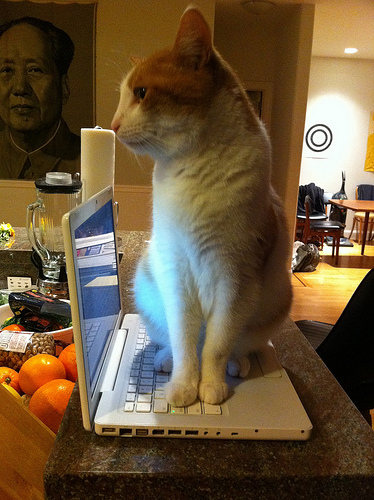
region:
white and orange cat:
[106, 19, 305, 407]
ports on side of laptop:
[94, 415, 317, 441]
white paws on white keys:
[155, 368, 239, 415]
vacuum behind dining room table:
[325, 167, 353, 250]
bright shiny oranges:
[0, 357, 73, 427]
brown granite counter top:
[220, 444, 312, 488]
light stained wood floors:
[313, 272, 343, 311]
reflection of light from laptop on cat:
[125, 219, 200, 347]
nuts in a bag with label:
[1, 324, 60, 365]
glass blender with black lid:
[23, 168, 86, 301]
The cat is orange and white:
[106, 30, 306, 406]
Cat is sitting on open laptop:
[62, 3, 331, 461]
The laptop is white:
[64, 201, 141, 428]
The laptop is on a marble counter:
[61, 400, 373, 473]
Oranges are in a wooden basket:
[4, 355, 79, 474]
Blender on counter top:
[18, 167, 76, 326]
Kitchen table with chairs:
[302, 167, 373, 266]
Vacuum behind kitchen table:
[324, 166, 356, 254]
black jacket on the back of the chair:
[350, 181, 372, 228]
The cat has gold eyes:
[116, 55, 164, 114]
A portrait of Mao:
[1, 3, 128, 192]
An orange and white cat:
[116, 21, 301, 406]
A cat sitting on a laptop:
[48, 3, 343, 444]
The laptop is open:
[56, 185, 317, 430]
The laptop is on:
[68, 206, 144, 388]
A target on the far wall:
[303, 119, 341, 153]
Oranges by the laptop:
[3, 347, 97, 432]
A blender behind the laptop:
[22, 162, 83, 273]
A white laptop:
[48, 184, 326, 452]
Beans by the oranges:
[1, 325, 65, 367]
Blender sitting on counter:
[23, 171, 71, 299]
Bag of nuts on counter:
[0, 329, 57, 370]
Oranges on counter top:
[0, 345, 81, 431]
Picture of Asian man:
[0, 2, 88, 178]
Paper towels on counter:
[78, 125, 117, 206]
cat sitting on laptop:
[71, 15, 310, 437]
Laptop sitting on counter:
[69, 186, 370, 478]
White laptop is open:
[63, 189, 314, 445]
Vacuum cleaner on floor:
[329, 170, 354, 247]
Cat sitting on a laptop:
[111, 30, 299, 407]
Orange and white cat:
[103, 37, 237, 165]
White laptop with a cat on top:
[86, 176, 309, 450]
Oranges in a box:
[7, 323, 70, 443]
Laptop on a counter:
[88, 194, 319, 440]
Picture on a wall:
[312, 121, 331, 151]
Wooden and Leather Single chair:
[305, 190, 346, 263]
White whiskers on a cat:
[117, 115, 178, 170]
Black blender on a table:
[37, 165, 72, 307]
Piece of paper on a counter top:
[1, 219, 18, 246]